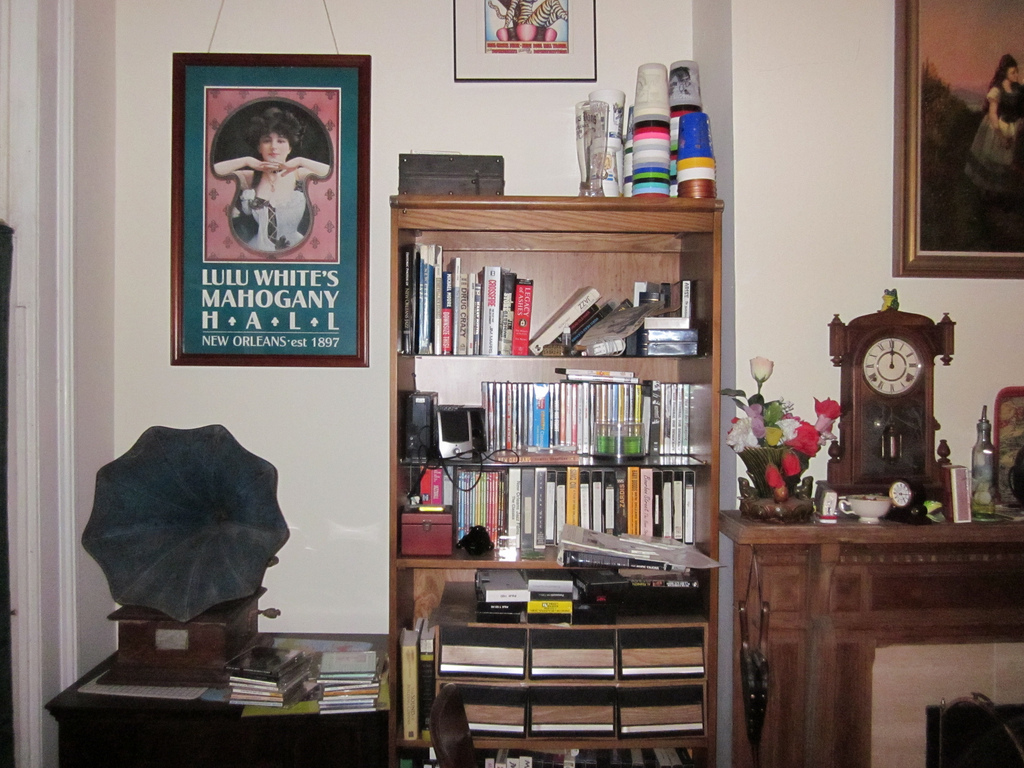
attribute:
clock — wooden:
[754, 262, 979, 509]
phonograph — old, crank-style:
[78, 417, 291, 690]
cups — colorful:
[621, 54, 721, 206]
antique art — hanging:
[168, 58, 365, 366]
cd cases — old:
[433, 610, 708, 746]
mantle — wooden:
[706, 509, 1018, 620]